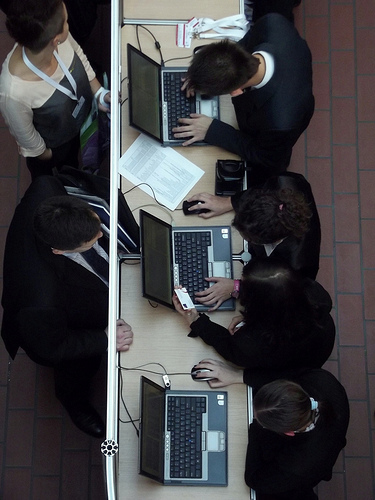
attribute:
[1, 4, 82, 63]
hair — brown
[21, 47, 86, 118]
necklace — white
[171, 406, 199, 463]
buttons — black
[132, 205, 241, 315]
laptop — black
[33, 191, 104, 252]
hair — brown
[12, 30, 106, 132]
band — white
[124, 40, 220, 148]
laptop — grey, dark grey, black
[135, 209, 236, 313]
laptop — grey, dark grey, black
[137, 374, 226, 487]
laptop — grey, dark grey, black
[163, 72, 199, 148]
keyboard — black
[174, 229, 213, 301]
keyboard — black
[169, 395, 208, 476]
keyboard — black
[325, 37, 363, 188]
brick — red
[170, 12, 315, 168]
man — light skinned